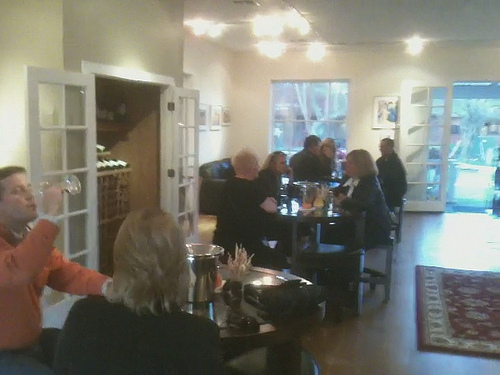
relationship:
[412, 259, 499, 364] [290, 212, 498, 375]
rug on floor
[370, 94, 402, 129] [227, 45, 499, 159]
picture on wall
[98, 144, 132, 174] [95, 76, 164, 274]
wine bottles in pantry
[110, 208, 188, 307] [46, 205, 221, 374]
head of woman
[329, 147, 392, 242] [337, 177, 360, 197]
woman wearing shirt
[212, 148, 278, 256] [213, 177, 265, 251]
women wearing shirt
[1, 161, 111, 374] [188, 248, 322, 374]
man at table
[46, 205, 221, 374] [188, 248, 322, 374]
woman at table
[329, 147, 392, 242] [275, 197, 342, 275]
woman at table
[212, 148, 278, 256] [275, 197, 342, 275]
women at table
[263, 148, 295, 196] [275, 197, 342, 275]
woman at table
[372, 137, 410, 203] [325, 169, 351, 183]
man at table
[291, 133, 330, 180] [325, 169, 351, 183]
man at table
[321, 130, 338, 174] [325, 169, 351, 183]
woman at table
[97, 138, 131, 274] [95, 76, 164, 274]
wine rack in pantry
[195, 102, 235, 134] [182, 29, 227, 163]
pictures on wall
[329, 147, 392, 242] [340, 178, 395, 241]
woman wearing jacket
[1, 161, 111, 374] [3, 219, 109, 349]
man wearing sweater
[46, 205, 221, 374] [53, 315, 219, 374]
woman wearing shirt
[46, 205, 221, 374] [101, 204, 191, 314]
woman has hair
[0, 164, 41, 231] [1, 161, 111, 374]
head of man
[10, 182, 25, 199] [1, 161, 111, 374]
eye of man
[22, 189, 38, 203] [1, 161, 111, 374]
nose of man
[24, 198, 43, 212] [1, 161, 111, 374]
mouth of man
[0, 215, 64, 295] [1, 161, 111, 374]
arm of man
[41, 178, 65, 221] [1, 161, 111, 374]
hand of man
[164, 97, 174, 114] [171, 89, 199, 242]
hinge on door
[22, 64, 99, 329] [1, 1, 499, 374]
french door in restaurant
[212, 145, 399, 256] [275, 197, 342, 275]
women at table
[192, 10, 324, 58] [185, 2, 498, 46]
light fixtures on ceiling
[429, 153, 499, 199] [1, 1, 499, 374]
patio of restaurant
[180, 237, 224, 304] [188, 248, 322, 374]
ice bucket on table